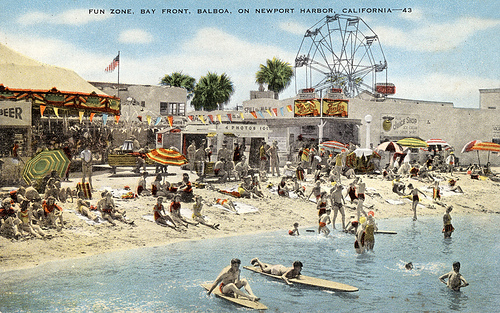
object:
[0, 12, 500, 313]
park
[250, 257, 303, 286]
man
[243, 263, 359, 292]
surfboard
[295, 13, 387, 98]
ride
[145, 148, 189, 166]
umbrella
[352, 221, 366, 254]
woman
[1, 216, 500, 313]
water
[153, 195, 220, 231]
women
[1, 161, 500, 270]
beach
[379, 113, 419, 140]
sign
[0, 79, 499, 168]
building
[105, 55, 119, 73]
flag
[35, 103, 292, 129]
string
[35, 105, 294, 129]
flags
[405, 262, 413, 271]
head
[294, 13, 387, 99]
ferris wheel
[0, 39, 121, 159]
merry-go-round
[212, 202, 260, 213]
towel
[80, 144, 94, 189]
person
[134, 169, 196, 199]
people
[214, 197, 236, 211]
person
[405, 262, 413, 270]
person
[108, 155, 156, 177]
bench